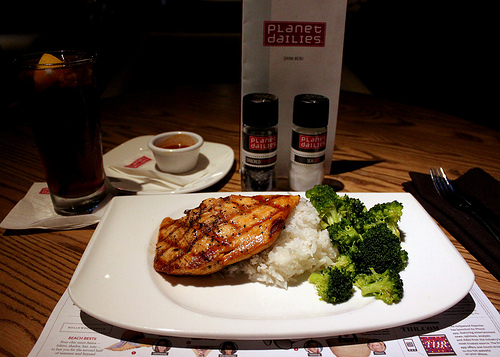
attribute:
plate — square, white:
[70, 193, 476, 338]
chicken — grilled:
[153, 196, 300, 278]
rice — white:
[223, 192, 338, 286]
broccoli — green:
[306, 183, 408, 306]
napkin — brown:
[403, 166, 500, 284]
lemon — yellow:
[37, 53, 65, 81]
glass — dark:
[17, 51, 111, 212]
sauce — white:
[148, 132, 202, 173]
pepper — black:
[242, 92, 278, 196]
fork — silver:
[430, 167, 500, 236]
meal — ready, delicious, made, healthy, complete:
[155, 185, 407, 308]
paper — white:
[26, 281, 499, 355]